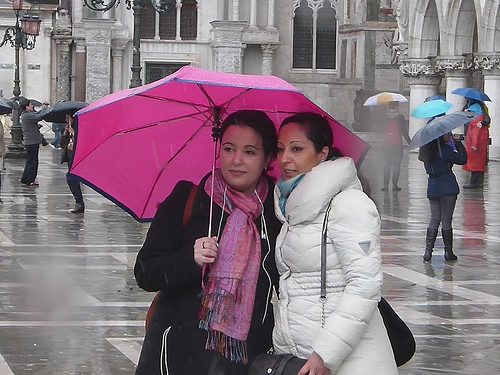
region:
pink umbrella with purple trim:
[65, 62, 369, 222]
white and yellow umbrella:
[362, 91, 405, 104]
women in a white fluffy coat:
[276, 110, 396, 373]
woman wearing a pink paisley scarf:
[132, 109, 277, 374]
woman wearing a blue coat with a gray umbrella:
[409, 113, 466, 263]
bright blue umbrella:
[411, 99, 451, 120]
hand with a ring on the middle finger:
[194, 234, 218, 262]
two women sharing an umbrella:
[68, 63, 395, 373]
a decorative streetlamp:
[0, 0, 26, 159]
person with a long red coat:
[464, 104, 490, 189]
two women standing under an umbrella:
[75, 65, 398, 374]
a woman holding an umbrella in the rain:
[410, 109, 472, 264]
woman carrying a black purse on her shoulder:
[322, 192, 416, 368]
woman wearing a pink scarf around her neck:
[206, 168, 268, 362]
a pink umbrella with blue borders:
[73, 57, 368, 222]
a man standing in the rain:
[16, 95, 43, 192]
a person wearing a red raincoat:
[463, 118, 488, 170]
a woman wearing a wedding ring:
[198, 238, 210, 253]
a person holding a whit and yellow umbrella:
[364, 84, 408, 119]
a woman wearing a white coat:
[274, 156, 397, 373]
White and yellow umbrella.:
[360, 90, 407, 107]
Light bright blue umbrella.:
[407, 97, 452, 113]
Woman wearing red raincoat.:
[463, 103, 490, 193]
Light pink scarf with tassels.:
[197, 175, 275, 357]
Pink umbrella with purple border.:
[67, 63, 372, 223]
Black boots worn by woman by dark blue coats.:
[419, 224, 459, 264]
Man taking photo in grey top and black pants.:
[17, 95, 52, 187]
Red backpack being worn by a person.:
[380, 118, 402, 147]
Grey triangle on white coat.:
[355, 237, 376, 257]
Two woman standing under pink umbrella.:
[66, 64, 420, 374]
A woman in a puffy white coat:
[276, 112, 381, 374]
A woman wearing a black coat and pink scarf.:
[131, 107, 274, 373]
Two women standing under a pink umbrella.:
[66, 65, 406, 373]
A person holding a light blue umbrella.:
[409, 97, 454, 117]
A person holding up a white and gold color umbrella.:
[362, 90, 407, 107]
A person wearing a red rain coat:
[465, 102, 490, 191]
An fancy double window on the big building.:
[286, 1, 343, 80]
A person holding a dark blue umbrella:
[451, 82, 493, 104]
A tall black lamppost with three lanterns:
[2, 1, 42, 161]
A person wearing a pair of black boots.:
[421, 225, 458, 263]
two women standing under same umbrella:
[75, 52, 426, 368]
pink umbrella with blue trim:
[66, 75, 373, 215]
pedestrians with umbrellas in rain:
[8, 73, 479, 350]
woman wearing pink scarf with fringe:
[158, 107, 276, 359]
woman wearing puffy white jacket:
[275, 106, 416, 368]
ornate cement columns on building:
[389, 3, 498, 161]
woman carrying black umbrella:
[402, 115, 487, 280]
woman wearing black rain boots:
[409, 113, 474, 276]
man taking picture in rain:
[11, 90, 58, 192]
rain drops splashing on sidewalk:
[20, 223, 107, 338]